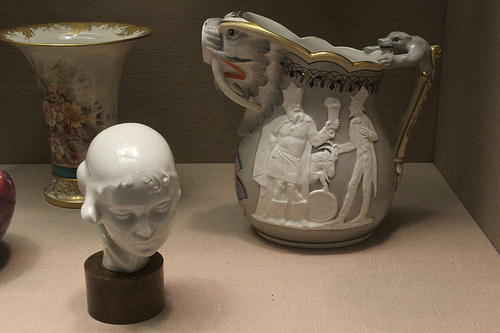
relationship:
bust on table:
[63, 109, 205, 322] [270, 289, 371, 309]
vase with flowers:
[0, 21, 154, 209] [42, 84, 71, 156]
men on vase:
[282, 99, 379, 215] [196, 20, 436, 247]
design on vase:
[232, 23, 412, 221] [196, 20, 436, 247]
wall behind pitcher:
[456, 50, 484, 102] [196, 3, 445, 259]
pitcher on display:
[197, 25, 470, 259] [32, 233, 484, 316]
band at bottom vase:
[51, 167, 71, 181] [15, 23, 138, 119]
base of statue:
[102, 281, 151, 316] [58, 116, 184, 319]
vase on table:
[0, 21, 154, 209] [18, 150, 411, 326]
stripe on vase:
[28, 161, 99, 191] [9, 11, 169, 217]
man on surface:
[267, 90, 338, 176] [238, 73, 344, 209]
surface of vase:
[238, 73, 344, 209] [202, 21, 451, 282]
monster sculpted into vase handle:
[371, 27, 434, 71] [191, 16, 459, 153]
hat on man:
[347, 87, 379, 112] [333, 88, 373, 123]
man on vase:
[333, 88, 373, 123] [200, 6, 463, 246]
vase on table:
[202, 21, 451, 282] [162, 140, 485, 330]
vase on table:
[28, 16, 164, 215] [18, 150, 411, 326]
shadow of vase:
[183, 185, 264, 259] [192, 5, 461, 273]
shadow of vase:
[358, 167, 479, 261] [202, 21, 451, 282]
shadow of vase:
[2, 167, 23, 281] [6, 232, 50, 299]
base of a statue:
[82, 249, 165, 325] [56, 106, 196, 286]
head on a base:
[61, 110, 181, 275] [70, 250, 194, 329]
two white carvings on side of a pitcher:
[259, 89, 378, 203] [223, 99, 423, 265]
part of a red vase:
[0, 142, 28, 263] [3, 229, 11, 248]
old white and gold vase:
[66, 99, 83, 131] [2, 57, 152, 136]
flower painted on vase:
[64, 76, 79, 92] [44, 100, 77, 167]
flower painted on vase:
[44, 73, 75, 106] [17, 99, 133, 105]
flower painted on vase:
[22, 71, 45, 95] [12, 99, 103, 109]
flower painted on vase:
[69, 99, 85, 117] [32, 106, 42, 126]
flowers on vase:
[30, 65, 73, 164] [26, 52, 102, 200]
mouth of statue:
[119, 195, 151, 250] [58, 116, 184, 319]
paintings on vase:
[49, 53, 142, 201] [15, 14, 167, 257]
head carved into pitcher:
[204, 15, 284, 117] [196, 3, 445, 259]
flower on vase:
[40, 79, 75, 132] [0, 8, 162, 208]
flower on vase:
[43, 73, 61, 98] [0, 8, 162, 208]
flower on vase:
[62, 105, 90, 134] [3, 19, 152, 206]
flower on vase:
[51, 119, 75, 141] [3, 19, 152, 206]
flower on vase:
[62, 104, 88, 128] [3, 19, 152, 206]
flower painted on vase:
[39, 99, 59, 129] [3, 19, 152, 206]